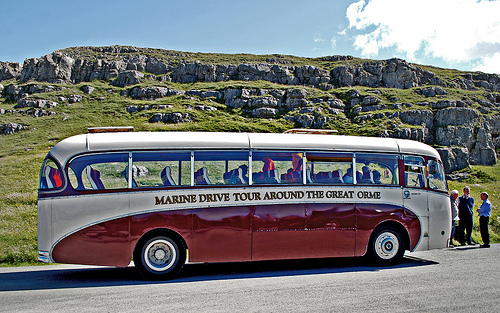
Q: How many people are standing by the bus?
A: 3.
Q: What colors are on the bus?
A: Red and white.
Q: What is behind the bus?
A: A rocky hill.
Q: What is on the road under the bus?
A: Its shadow.